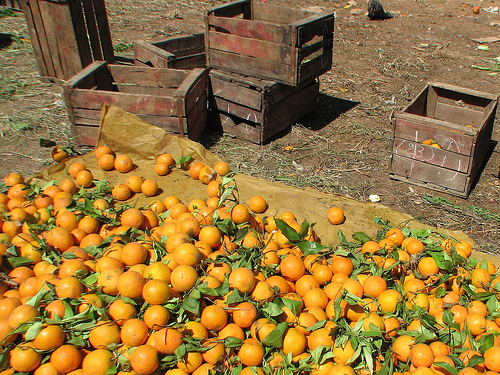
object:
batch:
[97, 232, 201, 301]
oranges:
[95, 267, 121, 298]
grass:
[0, 0, 500, 251]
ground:
[2, 0, 497, 254]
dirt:
[1, 0, 498, 259]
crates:
[388, 81, 500, 200]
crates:
[203, 0, 335, 87]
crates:
[206, 65, 318, 146]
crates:
[61, 60, 211, 148]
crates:
[131, 31, 207, 70]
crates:
[18, 0, 116, 85]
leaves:
[1, 145, 498, 375]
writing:
[393, 129, 462, 182]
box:
[388, 81, 500, 200]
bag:
[6, 104, 499, 267]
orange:
[248, 197, 267, 213]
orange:
[278, 255, 307, 280]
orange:
[378, 289, 403, 313]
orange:
[237, 341, 264, 367]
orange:
[129, 344, 158, 375]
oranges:
[56, 211, 79, 231]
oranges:
[141, 277, 169, 304]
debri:
[368, 194, 381, 202]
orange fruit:
[141, 178, 158, 195]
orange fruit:
[114, 154, 133, 173]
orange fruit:
[385, 228, 405, 247]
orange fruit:
[248, 195, 268, 212]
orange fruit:
[362, 275, 388, 298]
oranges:
[201, 304, 226, 331]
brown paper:
[276, 186, 305, 213]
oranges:
[301, 289, 331, 313]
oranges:
[213, 162, 230, 177]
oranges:
[75, 170, 91, 188]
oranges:
[42, 227, 73, 254]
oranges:
[52, 276, 84, 301]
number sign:
[214, 18, 277, 71]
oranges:
[300, 287, 328, 309]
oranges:
[143, 262, 172, 285]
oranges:
[467, 301, 488, 318]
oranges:
[53, 197, 74, 212]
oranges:
[176, 349, 202, 373]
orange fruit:
[327, 207, 346, 225]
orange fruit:
[170, 264, 197, 292]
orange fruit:
[127, 345, 162, 374]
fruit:
[0, 144, 500, 375]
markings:
[213, 16, 274, 66]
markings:
[397, 123, 462, 188]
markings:
[80, 94, 166, 146]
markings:
[41, 10, 73, 52]